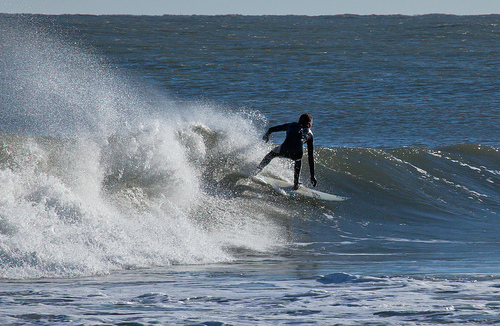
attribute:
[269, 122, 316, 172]
wetsuit — dark 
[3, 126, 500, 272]
waves — calm,  wave, white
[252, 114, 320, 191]
person — surfing, black, dark hair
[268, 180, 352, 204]
surfboard — white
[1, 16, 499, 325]
ocean — blue, calm, green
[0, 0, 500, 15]
sky — blue, clear